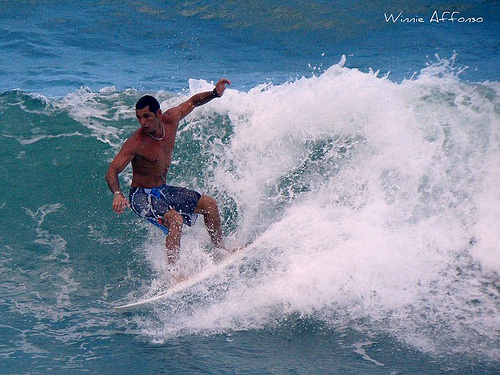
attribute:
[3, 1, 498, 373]
water — blue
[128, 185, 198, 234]
shorts — blue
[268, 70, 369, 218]
water — rough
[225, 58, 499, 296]
wave — white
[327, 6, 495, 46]
print — signed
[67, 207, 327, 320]
surferboard — white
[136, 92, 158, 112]
hair — brown